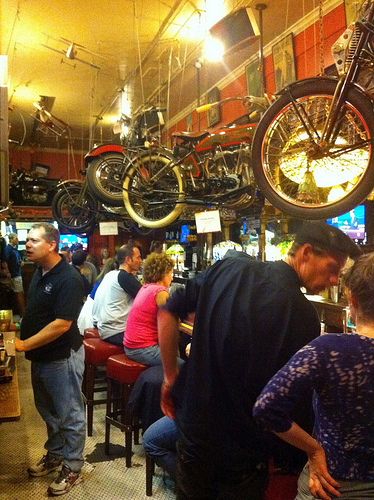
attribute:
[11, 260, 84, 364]
shirt — black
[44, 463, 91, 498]
shoe — tennis shoe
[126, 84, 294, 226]
motorcycle — small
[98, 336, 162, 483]
stool — bar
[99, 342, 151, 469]
stool — red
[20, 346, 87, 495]
jeans — blue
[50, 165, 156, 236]
motorcycle — small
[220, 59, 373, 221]
tire — black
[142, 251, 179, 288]
hair — frizzy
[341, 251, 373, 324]
hair — frizzy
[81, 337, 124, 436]
stool — red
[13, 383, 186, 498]
flooring — white, tiled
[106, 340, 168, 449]
stool — red, leather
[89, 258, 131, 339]
shirt — white, blue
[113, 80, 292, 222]
bicycle — silver, white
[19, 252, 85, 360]
shirt — black, short sleeved, collared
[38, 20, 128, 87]
airplane — model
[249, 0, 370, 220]
motorcycle — small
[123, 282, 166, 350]
tank top — pink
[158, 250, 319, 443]
shirt — black